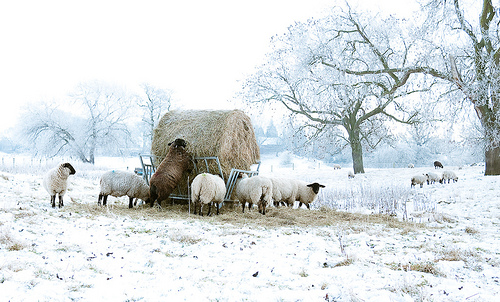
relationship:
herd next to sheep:
[45, 163, 75, 208] [96, 169, 151, 209]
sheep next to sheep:
[97, 171, 151, 208] [147, 137, 199, 208]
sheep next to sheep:
[187, 173, 227, 216] [235, 171, 275, 214]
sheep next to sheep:
[272, 174, 298, 209] [291, 178, 326, 213]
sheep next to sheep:
[187, 173, 227, 216] [270, 173, 298, 211]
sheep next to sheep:
[406, 172, 428, 190] [421, 167, 442, 187]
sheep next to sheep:
[423, 171, 444, 183] [439, 168, 460, 183]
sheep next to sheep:
[427, 166, 444, 183] [440, 169, 459, 183]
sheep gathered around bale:
[29, 154, 472, 222] [148, 106, 262, 181]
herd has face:
[45, 163, 75, 208] [58, 157, 75, 172]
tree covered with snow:
[240, 10, 452, 172] [244, 4, 409, 120]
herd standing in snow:
[45, 163, 75, 208] [0, 151, 499, 301]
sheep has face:
[293, 182, 325, 210] [309, 181, 319, 195]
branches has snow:
[254, 20, 434, 130] [244, 4, 409, 120]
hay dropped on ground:
[64, 196, 424, 230] [4, 156, 498, 300]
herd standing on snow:
[45, 163, 75, 208] [64, 217, 371, 280]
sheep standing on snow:
[97, 171, 151, 208] [64, 217, 371, 280]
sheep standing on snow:
[144, 133, 191, 212] [64, 217, 371, 280]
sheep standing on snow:
[187, 173, 227, 216] [64, 217, 371, 280]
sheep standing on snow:
[228, 161, 282, 211] [64, 217, 371, 280]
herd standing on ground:
[45, 163, 75, 208] [201, 213, 434, 300]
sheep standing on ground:
[97, 171, 151, 208] [201, 213, 434, 300]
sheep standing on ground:
[144, 133, 191, 212] [201, 213, 434, 300]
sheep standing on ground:
[187, 173, 227, 216] [201, 213, 434, 300]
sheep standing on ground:
[235, 173, 274, 216] [201, 213, 434, 300]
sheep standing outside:
[293, 182, 325, 210] [4, 12, 496, 296]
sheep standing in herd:
[144, 133, 191, 212] [33, 137, 466, 219]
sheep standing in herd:
[179, 161, 237, 223] [45, 138, 325, 214]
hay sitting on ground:
[143, 102, 271, 208] [2, 158, 385, 300]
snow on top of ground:
[0, 155, 500, 302] [25, 218, 376, 293]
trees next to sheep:
[272, 5, 498, 162] [406, 166, 458, 190]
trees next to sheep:
[16, 75, 149, 167] [49, 139, 190, 203]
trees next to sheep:
[272, 5, 498, 162] [193, 170, 326, 207]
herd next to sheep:
[45, 163, 75, 208] [95, 167, 156, 208]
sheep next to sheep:
[95, 167, 156, 208] [144, 133, 191, 212]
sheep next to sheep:
[144, 133, 191, 212] [187, 173, 227, 216]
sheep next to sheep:
[187, 173, 227, 216] [232, 167, 277, 213]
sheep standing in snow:
[42, 137, 458, 215] [0, 151, 499, 301]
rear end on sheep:
[189, 172, 212, 211] [192, 170, 227, 213]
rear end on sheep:
[253, 175, 270, 210] [237, 171, 273, 213]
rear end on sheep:
[148, 174, 165, 206] [270, 173, 296, 207]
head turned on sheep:
[59, 160, 77, 177] [49, 161, 75, 202]